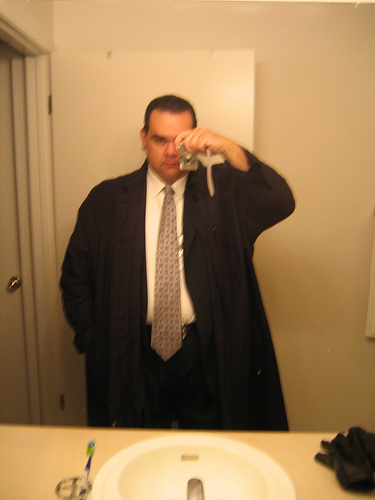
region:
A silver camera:
[174, 140, 199, 171]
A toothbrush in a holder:
[75, 438, 98, 495]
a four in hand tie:
[148, 185, 193, 365]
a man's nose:
[161, 139, 178, 156]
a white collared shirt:
[136, 167, 197, 333]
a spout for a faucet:
[180, 475, 208, 498]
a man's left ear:
[135, 126, 149, 151]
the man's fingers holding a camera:
[172, 127, 218, 157]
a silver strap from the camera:
[200, 142, 217, 196]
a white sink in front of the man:
[87, 433, 299, 499]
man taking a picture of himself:
[106, 101, 259, 251]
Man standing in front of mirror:
[99, 93, 311, 256]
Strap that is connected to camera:
[189, 139, 218, 203]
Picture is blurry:
[138, 112, 276, 273]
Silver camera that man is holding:
[156, 117, 255, 192]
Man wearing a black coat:
[69, 107, 189, 355]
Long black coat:
[34, 180, 295, 429]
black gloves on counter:
[235, 406, 370, 496]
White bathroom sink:
[106, 437, 263, 497]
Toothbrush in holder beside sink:
[54, 420, 101, 493]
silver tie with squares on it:
[148, 184, 184, 362]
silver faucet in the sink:
[184, 474, 205, 498]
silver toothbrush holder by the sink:
[53, 474, 94, 498]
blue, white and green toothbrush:
[77, 438, 96, 498]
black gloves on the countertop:
[310, 425, 374, 494]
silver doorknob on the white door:
[5, 272, 22, 292]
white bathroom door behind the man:
[44, 46, 257, 424]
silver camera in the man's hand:
[175, 138, 216, 196]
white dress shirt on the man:
[144, 164, 197, 329]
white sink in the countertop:
[85, 431, 295, 498]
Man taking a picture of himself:
[98, 82, 264, 302]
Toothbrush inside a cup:
[41, 434, 90, 494]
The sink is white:
[99, 402, 234, 497]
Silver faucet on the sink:
[180, 468, 206, 497]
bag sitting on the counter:
[315, 400, 371, 484]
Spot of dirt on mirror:
[244, 357, 276, 384]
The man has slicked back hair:
[130, 88, 201, 187]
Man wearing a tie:
[141, 230, 202, 362]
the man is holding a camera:
[150, 134, 213, 169]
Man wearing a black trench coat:
[65, 175, 325, 409]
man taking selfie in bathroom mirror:
[58, 91, 290, 432]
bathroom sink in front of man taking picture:
[3, 423, 370, 498]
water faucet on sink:
[180, 478, 206, 498]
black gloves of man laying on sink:
[315, 425, 373, 495]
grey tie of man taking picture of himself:
[150, 186, 183, 359]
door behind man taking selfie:
[48, 54, 140, 168]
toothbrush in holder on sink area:
[79, 439, 99, 480]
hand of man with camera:
[174, 127, 225, 170]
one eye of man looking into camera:
[148, 134, 167, 145]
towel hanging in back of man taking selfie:
[365, 239, 373, 337]